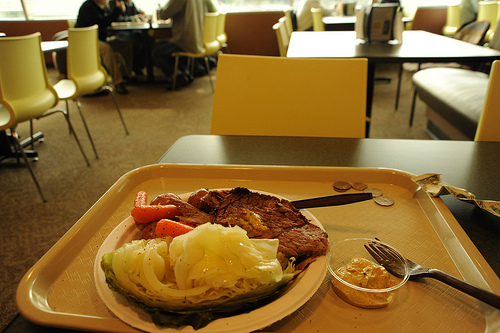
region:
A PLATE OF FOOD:
[90, 183, 375, 329]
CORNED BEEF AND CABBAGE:
[95, 176, 330, 321]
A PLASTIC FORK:
[365, 231, 495, 318]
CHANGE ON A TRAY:
[321, 171, 403, 216]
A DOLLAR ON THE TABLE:
[396, 161, 491, 216]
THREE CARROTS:
[120, 180, 191, 240]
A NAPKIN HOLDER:
[335, 0, 412, 45]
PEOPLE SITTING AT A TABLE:
[65, 1, 221, 96]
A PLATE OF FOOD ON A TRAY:
[15, 132, 486, 327]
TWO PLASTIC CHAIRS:
[2, 18, 158, 210]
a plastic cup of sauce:
[330, 236, 407, 309]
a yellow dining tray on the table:
[11, 163, 498, 331]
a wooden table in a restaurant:
[5, 134, 498, 331]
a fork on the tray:
[364, 236, 498, 314]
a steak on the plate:
[189, 187, 329, 259]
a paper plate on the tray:
[93, 184, 331, 330]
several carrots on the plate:
[133, 190, 195, 238]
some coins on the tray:
[334, 179, 394, 206]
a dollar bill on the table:
[414, 171, 498, 220]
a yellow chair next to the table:
[211, 54, 368, 144]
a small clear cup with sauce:
[334, 229, 428, 321]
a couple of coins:
[330, 156, 404, 226]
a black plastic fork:
[367, 233, 498, 315]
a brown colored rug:
[59, 116, 129, 219]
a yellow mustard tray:
[97, 146, 250, 192]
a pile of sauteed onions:
[111, 218, 256, 300]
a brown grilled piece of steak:
[212, 160, 329, 266]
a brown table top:
[210, 138, 317, 162]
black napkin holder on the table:
[350, 4, 425, 44]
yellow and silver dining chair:
[61, 26, 128, 149]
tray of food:
[17, 155, 499, 331]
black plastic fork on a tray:
[361, 230, 498, 317]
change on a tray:
[328, 176, 395, 208]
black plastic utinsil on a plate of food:
[280, 191, 381, 210]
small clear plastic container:
[325, 232, 410, 309]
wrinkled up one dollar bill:
[414, 168, 499, 218]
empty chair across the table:
[210, 47, 372, 144]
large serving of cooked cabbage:
[100, 220, 300, 326]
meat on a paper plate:
[161, 186, 330, 263]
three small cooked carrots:
[132, 187, 194, 242]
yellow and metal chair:
[48, 29, 138, 156]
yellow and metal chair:
[4, 31, 82, 192]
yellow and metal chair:
[186, 15, 214, 103]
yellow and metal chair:
[204, 44, 365, 132]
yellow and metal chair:
[265, 16, 292, 47]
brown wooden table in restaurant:
[286, 22, 488, 65]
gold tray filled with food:
[118, 150, 453, 331]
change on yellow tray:
[326, 177, 402, 217]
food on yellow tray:
[129, 187, 322, 330]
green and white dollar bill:
[403, 157, 497, 219]